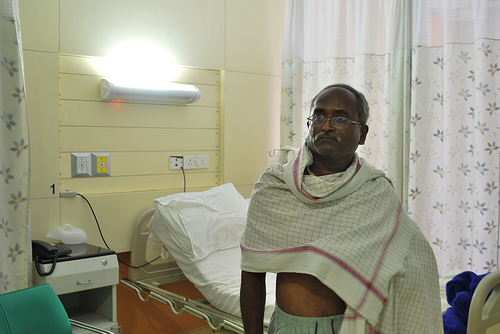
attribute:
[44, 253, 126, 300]
drawer — on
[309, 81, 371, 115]
grey hair — on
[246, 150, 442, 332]
sheet — on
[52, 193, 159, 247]
cord — on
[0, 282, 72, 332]
chair — green 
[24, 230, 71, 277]
phone — black 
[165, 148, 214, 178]
outlets — on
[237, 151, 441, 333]
robe — plaid 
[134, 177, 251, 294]
bed — with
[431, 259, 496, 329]
shirt — blue 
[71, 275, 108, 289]
knob — on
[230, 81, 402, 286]
man — Indian 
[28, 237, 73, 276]
telephone — black 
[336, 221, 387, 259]
sheet — on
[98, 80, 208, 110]
light — over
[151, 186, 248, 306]
bed — hospital 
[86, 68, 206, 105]
light — on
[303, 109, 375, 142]
glasses — on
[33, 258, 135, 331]
stand — night 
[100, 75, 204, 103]
light fixture — light 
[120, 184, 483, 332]
hospital bed — hospital 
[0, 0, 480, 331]
room — hospital 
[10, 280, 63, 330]
back — on